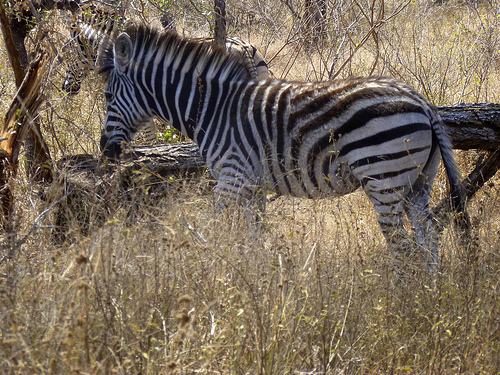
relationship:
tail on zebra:
[428, 118, 481, 258] [94, 30, 467, 292]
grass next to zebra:
[70, 233, 474, 375] [94, 30, 467, 292]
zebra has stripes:
[94, 30, 467, 292] [216, 88, 310, 152]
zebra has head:
[94, 30, 467, 292] [90, 49, 155, 150]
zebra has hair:
[94, 30, 467, 292] [296, 80, 345, 109]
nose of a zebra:
[98, 137, 119, 155] [94, 30, 467, 292]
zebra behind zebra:
[66, 8, 274, 87] [94, 30, 467, 292]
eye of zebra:
[103, 87, 116, 103] [94, 30, 467, 292]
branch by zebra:
[10, 41, 60, 163] [94, 30, 467, 292]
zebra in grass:
[94, 30, 467, 292] [70, 233, 474, 375]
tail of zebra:
[428, 118, 481, 258] [94, 30, 467, 292]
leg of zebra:
[368, 190, 419, 305] [94, 30, 467, 292]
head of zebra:
[90, 49, 155, 150] [94, 30, 467, 292]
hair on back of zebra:
[296, 80, 345, 109] [94, 30, 467, 292]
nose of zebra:
[98, 137, 119, 155] [94, 30, 467, 292]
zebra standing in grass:
[94, 30, 467, 292] [70, 233, 474, 375]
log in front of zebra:
[62, 97, 498, 198] [94, 30, 467, 292]